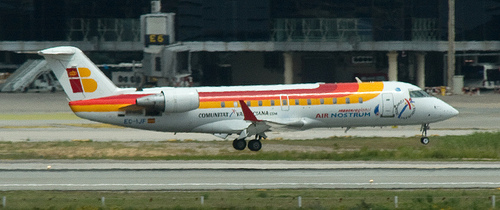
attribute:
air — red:
[312, 110, 331, 122]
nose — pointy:
[420, 97, 466, 124]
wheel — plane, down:
[419, 136, 431, 146]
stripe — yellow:
[71, 82, 384, 110]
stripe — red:
[70, 82, 361, 104]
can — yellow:
[440, 85, 449, 97]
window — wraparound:
[402, 87, 434, 100]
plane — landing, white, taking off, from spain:
[33, 40, 463, 147]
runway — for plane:
[5, 151, 500, 194]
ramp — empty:
[0, 50, 50, 95]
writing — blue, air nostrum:
[329, 112, 374, 120]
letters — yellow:
[146, 35, 167, 49]